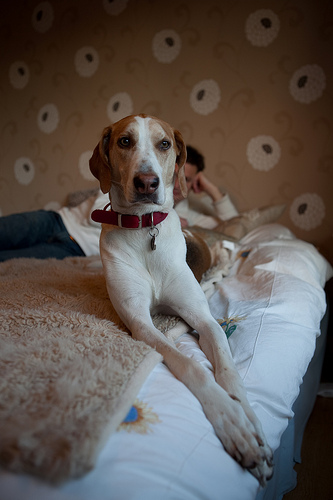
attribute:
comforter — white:
[102, 232, 332, 498]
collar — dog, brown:
[89, 203, 188, 229]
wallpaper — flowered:
[3, 2, 332, 205]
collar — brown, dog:
[92, 208, 167, 227]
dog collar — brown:
[89, 207, 167, 228]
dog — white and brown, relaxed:
[89, 112, 277, 487]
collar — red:
[87, 202, 181, 236]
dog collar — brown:
[90, 201, 168, 250]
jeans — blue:
[0, 209, 87, 276]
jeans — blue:
[9, 201, 81, 270]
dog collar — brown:
[89, 199, 189, 227]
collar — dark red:
[87, 199, 179, 233]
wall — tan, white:
[0, 0, 332, 246]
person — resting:
[0, 138, 246, 266]